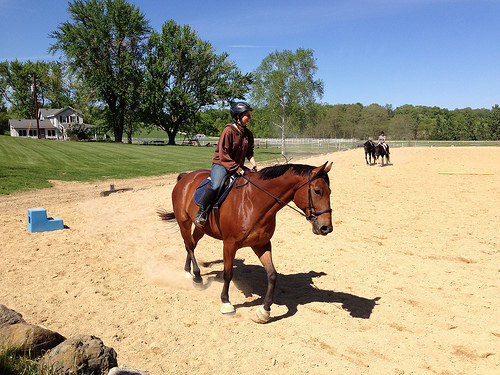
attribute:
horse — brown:
[228, 149, 344, 275]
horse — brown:
[155, 155, 331, 286]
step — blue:
[19, 198, 51, 238]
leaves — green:
[97, 44, 176, 111]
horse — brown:
[223, 169, 363, 296]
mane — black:
[249, 158, 308, 188]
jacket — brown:
[210, 114, 255, 174]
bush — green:
[471, 104, 497, 140]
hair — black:
[257, 160, 324, 181]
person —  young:
[192, 99, 260, 228]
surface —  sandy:
[0, 144, 499, 373]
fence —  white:
[93, 134, 366, 145]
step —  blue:
[27, 205, 48, 220]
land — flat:
[3, 125, 494, 306]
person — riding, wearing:
[190, 88, 262, 238]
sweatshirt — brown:
[197, 121, 257, 187]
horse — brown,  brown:
[156, 158, 335, 324]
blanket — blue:
[191, 178, 231, 207]